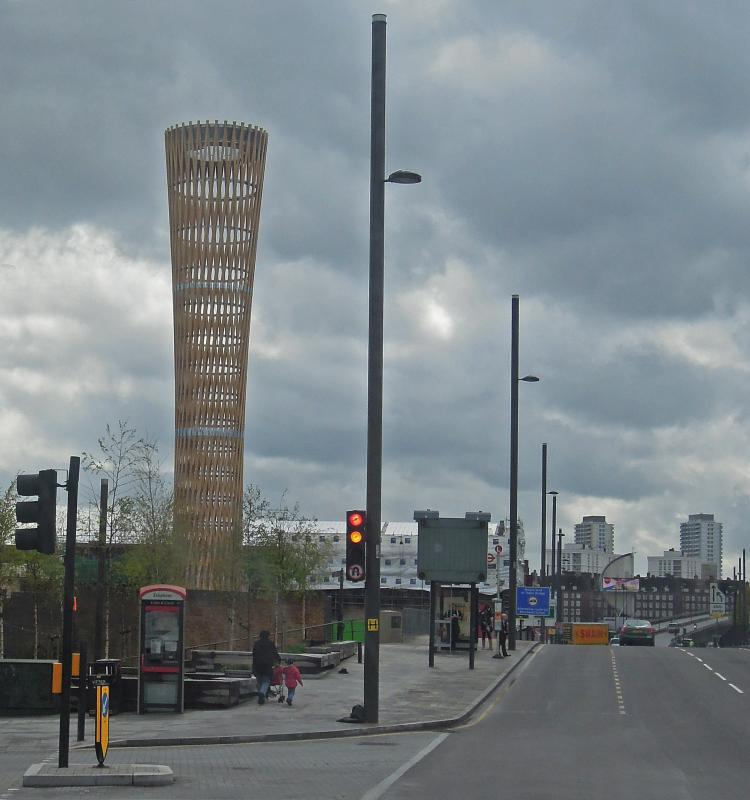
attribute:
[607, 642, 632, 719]
line — yellow, dotted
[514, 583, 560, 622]
sign — informational, blue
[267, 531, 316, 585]
leaves — green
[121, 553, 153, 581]
leaves — green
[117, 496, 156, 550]
leaves — green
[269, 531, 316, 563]
leaves — green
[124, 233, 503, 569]
pole — tall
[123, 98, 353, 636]
building — city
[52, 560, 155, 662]
leaves — green 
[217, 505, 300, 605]
leaves — green 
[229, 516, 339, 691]
leaves — green 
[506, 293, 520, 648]
light post — tall, black